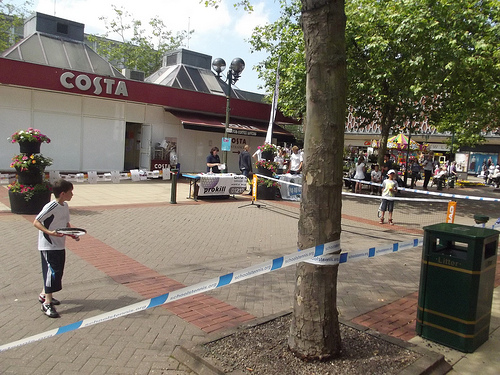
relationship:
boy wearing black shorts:
[28, 177, 78, 316] [44, 245, 71, 301]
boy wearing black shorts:
[378, 165, 402, 221] [382, 196, 394, 213]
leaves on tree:
[250, 1, 497, 156] [248, 0, 499, 167]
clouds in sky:
[235, 2, 269, 39] [0, 0, 304, 93]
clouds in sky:
[36, 2, 230, 33] [0, 0, 304, 93]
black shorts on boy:
[41, 249, 67, 296] [28, 160, 113, 345]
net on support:
[247, 172, 457, 238] [443, 198, 455, 225]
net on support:
[247, 172, 457, 238] [236, 173, 266, 208]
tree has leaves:
[266, 2, 493, 173] [354, 17, 487, 111]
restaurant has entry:
[0, 12, 300, 182] [122, 121, 140, 171]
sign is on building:
[58, 72, 128, 97] [0, 12, 302, 182]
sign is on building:
[230, 137, 247, 146] [0, 12, 302, 182]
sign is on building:
[152, 163, 169, 171] [0, 12, 302, 182]